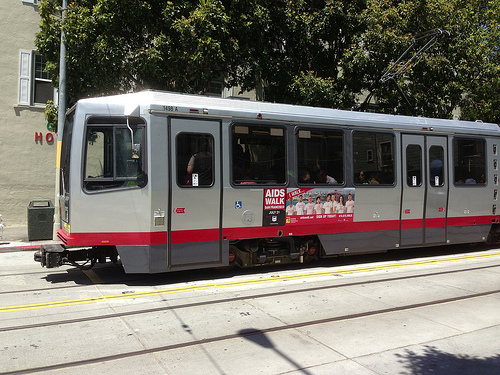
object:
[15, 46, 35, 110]
shutter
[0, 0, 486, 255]
building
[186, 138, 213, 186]
person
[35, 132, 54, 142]
h o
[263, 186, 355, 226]
poster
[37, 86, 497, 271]
streetcar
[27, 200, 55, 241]
trash bin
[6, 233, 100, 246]
sidewalk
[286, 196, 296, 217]
people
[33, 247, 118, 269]
handleconnector post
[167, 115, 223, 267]
door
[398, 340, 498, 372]
shadow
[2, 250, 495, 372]
shadow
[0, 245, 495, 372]
pavement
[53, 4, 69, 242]
light pole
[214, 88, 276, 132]
wall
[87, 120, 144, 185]
window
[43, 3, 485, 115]
leaves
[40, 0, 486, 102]
tree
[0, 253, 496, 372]
concrete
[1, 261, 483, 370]
tracks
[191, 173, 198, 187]
sign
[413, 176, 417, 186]
sign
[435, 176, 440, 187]
sign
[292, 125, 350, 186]
window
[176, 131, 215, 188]
window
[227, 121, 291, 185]
window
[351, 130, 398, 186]
window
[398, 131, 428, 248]
door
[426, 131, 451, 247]
door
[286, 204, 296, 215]
t-shirts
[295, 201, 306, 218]
t-shirts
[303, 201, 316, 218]
t-shirts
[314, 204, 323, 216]
t-shirts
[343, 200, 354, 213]
t-shirts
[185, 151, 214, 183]
shirt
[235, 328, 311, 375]
shadow